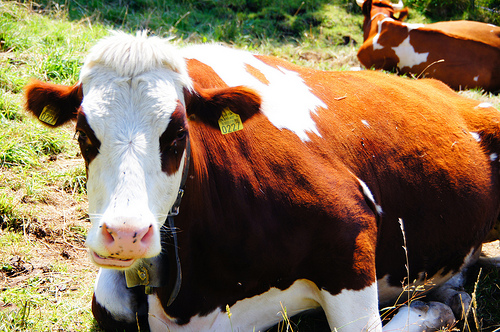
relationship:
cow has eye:
[74, 33, 488, 318] [170, 126, 188, 143]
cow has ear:
[74, 33, 488, 318] [183, 84, 263, 129]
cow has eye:
[74, 33, 488, 318] [75, 127, 95, 149]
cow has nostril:
[74, 33, 488, 318] [141, 223, 157, 243]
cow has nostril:
[74, 33, 488, 318] [101, 221, 116, 245]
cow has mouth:
[74, 33, 488, 318] [90, 248, 136, 267]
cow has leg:
[74, 33, 488, 318] [316, 267, 456, 331]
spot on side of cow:
[360, 118, 370, 126] [74, 33, 488, 318]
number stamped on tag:
[222, 121, 241, 134] [216, 106, 244, 136]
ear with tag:
[183, 84, 263, 129] [216, 106, 244, 136]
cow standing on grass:
[74, 33, 488, 318] [0, 0, 499, 331]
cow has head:
[74, 33, 488, 318] [24, 28, 264, 271]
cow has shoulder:
[74, 33, 488, 318] [294, 170, 379, 294]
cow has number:
[74, 33, 488, 318] [222, 121, 241, 134]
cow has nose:
[74, 33, 488, 318] [100, 222, 154, 258]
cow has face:
[74, 33, 488, 318] [75, 97, 189, 271]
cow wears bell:
[74, 33, 488, 318] [123, 249, 167, 294]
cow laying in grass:
[74, 33, 488, 318] [0, 0, 499, 331]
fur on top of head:
[84, 28, 189, 78] [24, 28, 264, 271]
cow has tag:
[74, 33, 488, 318] [39, 105, 59, 127]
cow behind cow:
[355, 0, 499, 94] [74, 33, 488, 318]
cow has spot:
[74, 33, 488, 318] [349, 169, 384, 214]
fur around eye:
[159, 98, 188, 177] [170, 126, 188, 143]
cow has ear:
[74, 33, 488, 318] [25, 80, 84, 129]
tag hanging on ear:
[216, 106, 244, 136] [183, 84, 263, 129]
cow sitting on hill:
[74, 33, 488, 318] [1, 1, 500, 331]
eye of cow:
[75, 127, 95, 149] [74, 33, 488, 318]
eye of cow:
[170, 126, 188, 143] [74, 33, 488, 318]